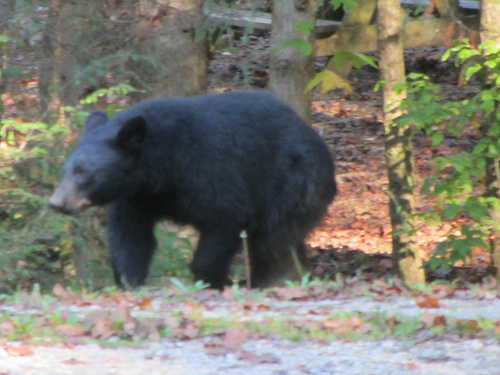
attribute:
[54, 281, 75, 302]
leaf — brown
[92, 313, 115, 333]
leaf — brown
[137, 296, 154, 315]
leaf — brown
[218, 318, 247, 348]
leaf — brown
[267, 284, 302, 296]
leaf — brown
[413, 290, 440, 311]
leaf — brown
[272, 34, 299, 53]
leaf — green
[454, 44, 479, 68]
leaf — green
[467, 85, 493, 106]
leaf — green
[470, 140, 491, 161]
leaf — green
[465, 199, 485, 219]
leaf — green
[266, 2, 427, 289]
tree — large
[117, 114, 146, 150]
ear — black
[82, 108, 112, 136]
ear — black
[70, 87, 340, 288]
fur — black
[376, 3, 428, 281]
trunk — brown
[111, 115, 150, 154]
ear —   bear's,    two,  black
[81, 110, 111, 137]
ear —   bear's,  black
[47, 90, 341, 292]
bear — furry, black, large, huge, walking, big, standing, medium,  black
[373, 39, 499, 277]
leaves — green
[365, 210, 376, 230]
leaf — dry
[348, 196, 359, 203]
leaf — dry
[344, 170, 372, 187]
leaf — dry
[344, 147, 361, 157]
leaf — dry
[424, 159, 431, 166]
leaf — dry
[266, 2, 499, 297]
tree —  thin,  brown,  small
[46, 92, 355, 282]
bear — big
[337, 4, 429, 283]
tree —  brown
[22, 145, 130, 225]
eyes — open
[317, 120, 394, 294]
leaves —  dead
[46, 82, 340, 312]
bear — medium, brown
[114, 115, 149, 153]
ear — furry, black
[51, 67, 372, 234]
bear — big, black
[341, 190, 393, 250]
leaves — dry, brown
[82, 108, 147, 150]
ears —  two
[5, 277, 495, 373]
road — gravel, dirt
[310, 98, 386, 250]
floor — of forest